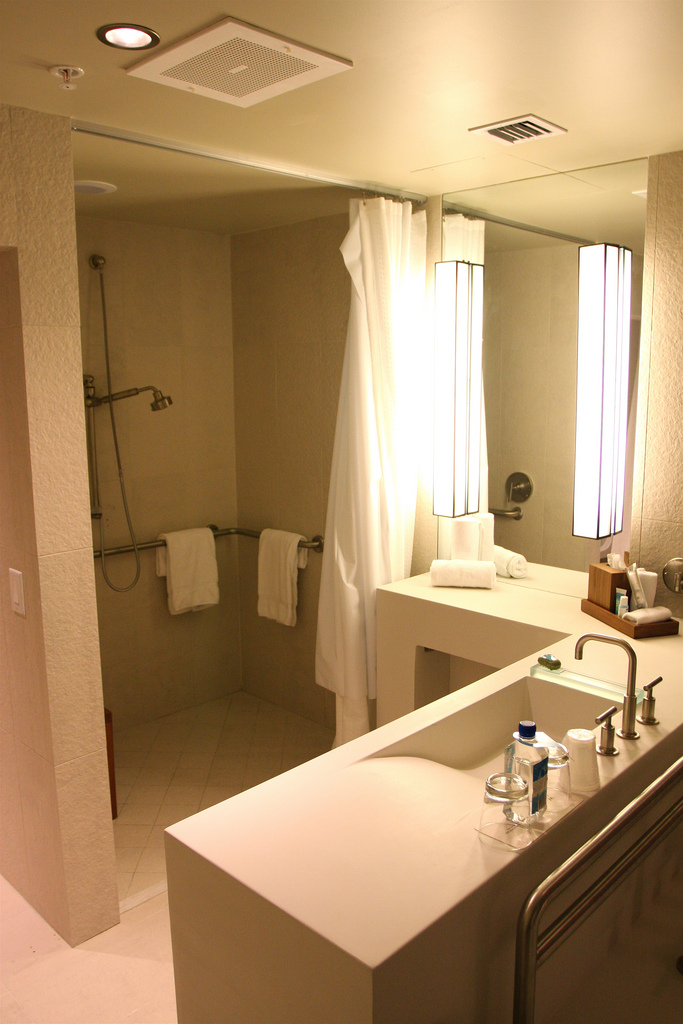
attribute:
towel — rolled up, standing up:
[401, 497, 527, 578]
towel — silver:
[239, 521, 326, 592]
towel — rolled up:
[231, 501, 291, 607]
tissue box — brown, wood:
[579, 552, 666, 635]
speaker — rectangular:
[120, 14, 354, 116]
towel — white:
[252, 526, 309, 625]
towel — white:
[428, 557, 491, 591]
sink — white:
[367, 661, 650, 826]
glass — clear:
[489, 774, 529, 854]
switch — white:
[8, 566, 26, 622]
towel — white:
[153, 522, 223, 617]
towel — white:
[257, 530, 313, 633]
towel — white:
[427, 557, 496, 589]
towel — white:
[490, 541, 530, 581]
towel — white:
[448, 510, 493, 556]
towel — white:
[473, 512, 492, 560]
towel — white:
[621, 598, 669, 622]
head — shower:
[138, 373, 183, 422]